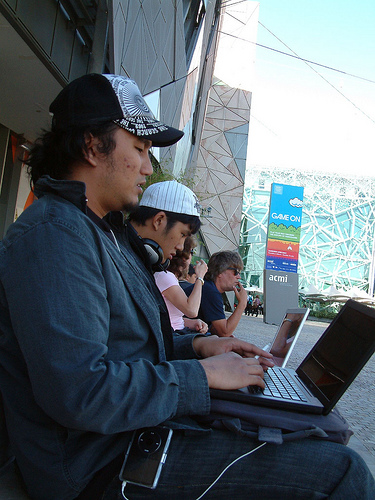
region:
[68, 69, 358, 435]
people are using the laptop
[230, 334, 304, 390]
the man is holding a cigarette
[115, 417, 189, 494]
the mp3 player is black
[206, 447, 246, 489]
the cord is white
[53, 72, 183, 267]
men is wearing caps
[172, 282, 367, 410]
the laptop is balck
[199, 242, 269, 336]
the man is smoking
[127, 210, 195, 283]
the headphone is on the man's neck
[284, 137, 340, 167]
the sky is white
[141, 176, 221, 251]
the cap is white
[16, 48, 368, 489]
people sitting outside of a convention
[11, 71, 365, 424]
man typing on a laptop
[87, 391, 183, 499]
portable music player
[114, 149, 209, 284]
man wearing white hat and headphones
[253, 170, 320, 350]
large sign with white lettering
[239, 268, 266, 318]
people walking in the background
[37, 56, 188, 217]
man wearing black hat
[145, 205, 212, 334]
woman wearing pink shirt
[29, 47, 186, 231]
man with long hair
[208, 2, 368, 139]
long metal cables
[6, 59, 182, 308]
a man wearing a ball cap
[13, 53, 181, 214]
a man with dark brown hair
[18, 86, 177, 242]
a man with acne on his face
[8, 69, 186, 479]
a man wearing a dark blue jacket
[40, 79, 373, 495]
a man wearing blue jeans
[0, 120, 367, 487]
a man using his lap top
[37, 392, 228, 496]
a man using his i pod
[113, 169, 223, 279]
a man with a striped ball cap on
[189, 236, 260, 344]
a man wearing brown sunglasses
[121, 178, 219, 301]
a man wearing headphones around his neck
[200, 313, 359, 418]
The man is typing on the laptop.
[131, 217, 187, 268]
The man has earphones around his neck.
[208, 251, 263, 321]
the man is touching his mouth.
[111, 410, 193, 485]
The man has Ipod attached to his laptop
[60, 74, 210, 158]
The man has on a black and white cap.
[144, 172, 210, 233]
The man is wearing a white cap.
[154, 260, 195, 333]
the lady is wearing a pink shirt.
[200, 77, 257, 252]
The building is made out of glass.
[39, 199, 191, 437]
The man is wearing a blue jacket.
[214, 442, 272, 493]
The cord is white.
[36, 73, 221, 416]
man in a black and white cap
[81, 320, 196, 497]
man with a black iPod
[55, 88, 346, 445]
men focused on their laptops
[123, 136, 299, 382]
man with headphones around neck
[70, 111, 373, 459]
people playing on their laptops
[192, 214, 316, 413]
a man staring off into space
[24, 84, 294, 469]
man with somewhat long hair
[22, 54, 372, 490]
a very sunny day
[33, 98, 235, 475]
man in a blue jacket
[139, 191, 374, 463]
man with a black laptop